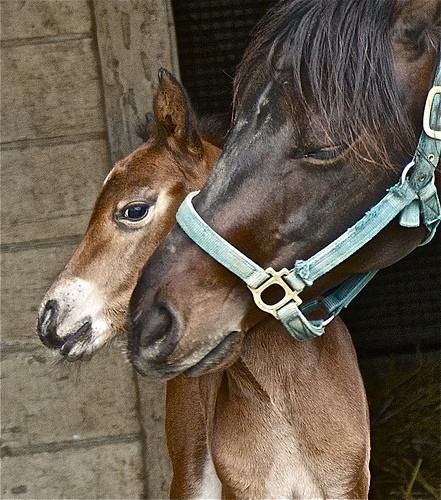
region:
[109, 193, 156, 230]
foal's left eye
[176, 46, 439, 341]
green bridle on brown horse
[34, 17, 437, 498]
brown horse with tan foal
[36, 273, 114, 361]
white mouth area of foal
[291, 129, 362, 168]
brown horse's left eye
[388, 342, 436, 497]
straw on floor in background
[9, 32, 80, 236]
tan boards to the upper left of foal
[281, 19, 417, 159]
part of brown horse's mane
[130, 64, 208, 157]
foal's ears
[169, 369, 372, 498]
foal's body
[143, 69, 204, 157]
The brown ear of a calf.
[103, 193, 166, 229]
The black eye of a calf.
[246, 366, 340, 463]
The brown fur of a calf.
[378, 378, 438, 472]
Straw on the ground.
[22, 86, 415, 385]
Mama horse nuzzles baby calf.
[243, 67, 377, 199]
Horse is dark brown.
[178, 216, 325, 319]
Reigns are light blue.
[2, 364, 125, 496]
The stable wall.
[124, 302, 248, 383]
Horse nose and mouth.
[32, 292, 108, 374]
Calf nose and mouth.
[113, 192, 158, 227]
the eye of a horse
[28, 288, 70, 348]
the nose of a horse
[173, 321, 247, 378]
the mouth of a horse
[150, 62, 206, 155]
the ear of a horse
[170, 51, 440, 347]
the bridle of a horse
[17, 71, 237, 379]
the head of a horse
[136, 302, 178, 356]
the nostril of a horse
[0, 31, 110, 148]
a board on the wall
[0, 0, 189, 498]
a tan wooden wall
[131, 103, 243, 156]
the mane of a horse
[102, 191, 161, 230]
a black horse eye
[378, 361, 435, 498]
a pile of brown hay on ground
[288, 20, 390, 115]
brown hair on a horse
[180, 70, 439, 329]
a horse with blue reigns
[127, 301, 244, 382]
a large brown horse mouth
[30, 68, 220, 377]
face of a baby horse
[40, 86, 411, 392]
a large horse nuzzling a baby horse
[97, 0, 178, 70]
a wooden barn door frame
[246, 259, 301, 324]
a gold harness ring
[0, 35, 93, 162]
a brown wooden wall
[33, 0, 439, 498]
horse and pony in the barn's doorway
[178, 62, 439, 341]
blue bridle on horse's face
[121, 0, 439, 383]
brown and black horse's head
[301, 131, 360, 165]
closed eye on head of horse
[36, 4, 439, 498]
horse showing affection to the pony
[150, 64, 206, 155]
an ear on the pony's head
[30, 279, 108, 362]
white nose on pony's face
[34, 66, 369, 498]
brown and white pony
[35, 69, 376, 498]
pony in the doorway of stable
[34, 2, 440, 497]
horse trying to stop pony from coming outside